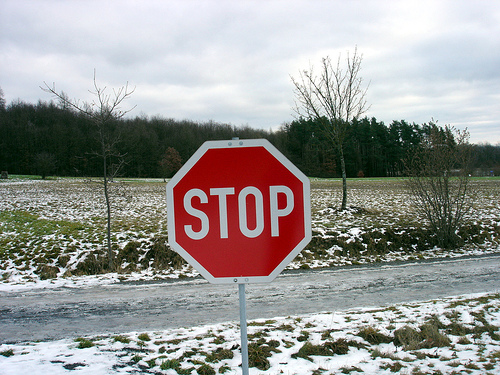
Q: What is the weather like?
A: It is cloudy.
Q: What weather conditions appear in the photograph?
A: It is cloudy.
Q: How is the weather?
A: It is cloudy.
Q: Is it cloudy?
A: Yes, it is cloudy.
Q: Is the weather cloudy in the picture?
A: Yes, it is cloudy.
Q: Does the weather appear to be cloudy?
A: Yes, it is cloudy.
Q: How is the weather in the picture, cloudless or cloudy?
A: It is cloudy.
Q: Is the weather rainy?
A: No, it is cloudy.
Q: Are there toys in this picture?
A: No, there are no toys.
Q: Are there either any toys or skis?
A: No, there are no toys or skis.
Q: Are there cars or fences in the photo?
A: No, there are no cars or fences.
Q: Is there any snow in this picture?
A: Yes, there is snow.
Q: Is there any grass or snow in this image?
A: Yes, there is snow.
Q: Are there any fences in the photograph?
A: No, there are no fences.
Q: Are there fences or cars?
A: No, there are no fences or cars.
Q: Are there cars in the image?
A: No, there are no cars.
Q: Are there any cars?
A: No, there are no cars.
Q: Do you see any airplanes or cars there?
A: No, there are no cars or airplanes.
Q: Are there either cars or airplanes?
A: No, there are no cars or airplanes.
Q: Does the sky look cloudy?
A: Yes, the sky is cloudy.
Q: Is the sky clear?
A: No, the sky is cloudy.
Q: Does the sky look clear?
A: No, the sky is cloudy.